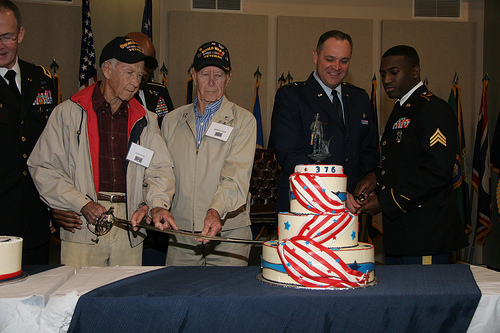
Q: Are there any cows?
A: No, there are no cows.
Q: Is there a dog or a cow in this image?
A: No, there are no cows or dogs.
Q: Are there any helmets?
A: No, there are no helmets.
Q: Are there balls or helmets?
A: No, there are no helmets or balls.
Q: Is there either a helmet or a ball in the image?
A: No, there are no helmets or balls.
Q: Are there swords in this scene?
A: Yes, there is a sword.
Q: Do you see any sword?
A: Yes, there is a sword.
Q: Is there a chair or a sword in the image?
A: Yes, there is a sword.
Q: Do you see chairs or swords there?
A: Yes, there is a sword.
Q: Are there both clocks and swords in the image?
A: No, there is a sword but no clocks.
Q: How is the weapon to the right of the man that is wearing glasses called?
A: The weapon is a sword.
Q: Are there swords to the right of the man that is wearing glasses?
A: Yes, there is a sword to the right of the man.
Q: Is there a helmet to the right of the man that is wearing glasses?
A: No, there is a sword to the right of the man.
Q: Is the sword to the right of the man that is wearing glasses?
A: Yes, the sword is to the right of the man.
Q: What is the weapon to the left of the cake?
A: The weapon is a sword.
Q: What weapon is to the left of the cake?
A: The weapon is a sword.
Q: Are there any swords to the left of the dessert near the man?
A: Yes, there is a sword to the left of the cake.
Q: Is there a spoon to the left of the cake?
A: No, there is a sword to the left of the cake.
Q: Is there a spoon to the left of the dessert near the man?
A: No, there is a sword to the left of the cake.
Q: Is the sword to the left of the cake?
A: Yes, the sword is to the left of the cake.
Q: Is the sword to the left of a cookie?
A: No, the sword is to the left of the cake.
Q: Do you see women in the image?
A: No, there are no women.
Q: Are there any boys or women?
A: No, there are no women or boys.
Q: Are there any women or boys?
A: No, there are no women or boys.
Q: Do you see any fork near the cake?
A: No, there is a man near the cake.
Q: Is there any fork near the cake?
A: No, there is a man near the cake.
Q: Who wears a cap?
A: The man wears a cap.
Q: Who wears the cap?
A: The man wears a cap.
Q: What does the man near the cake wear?
A: The man wears a cap.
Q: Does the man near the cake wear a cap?
A: Yes, the man wears a cap.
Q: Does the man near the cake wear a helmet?
A: No, the man wears a cap.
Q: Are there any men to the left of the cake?
A: Yes, there is a man to the left of the cake.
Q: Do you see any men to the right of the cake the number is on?
A: No, the man is to the left of the cake.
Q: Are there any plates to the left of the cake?
A: No, there is a man to the left of the cake.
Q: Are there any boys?
A: No, there are no boys.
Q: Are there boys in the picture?
A: No, there are no boys.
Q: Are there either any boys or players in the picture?
A: No, there are no boys or players.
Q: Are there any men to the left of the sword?
A: Yes, there is a man to the left of the sword.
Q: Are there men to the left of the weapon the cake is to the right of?
A: Yes, there is a man to the left of the sword.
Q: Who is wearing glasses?
A: The man is wearing glasses.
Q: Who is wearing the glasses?
A: The man is wearing glasses.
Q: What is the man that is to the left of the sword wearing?
A: The man is wearing glasses.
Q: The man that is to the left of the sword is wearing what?
A: The man is wearing glasses.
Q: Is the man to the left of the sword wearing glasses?
A: Yes, the man is wearing glasses.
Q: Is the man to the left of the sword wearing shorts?
A: No, the man is wearing glasses.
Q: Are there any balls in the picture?
A: No, there are no balls.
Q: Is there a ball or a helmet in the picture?
A: No, there are no balls or helmets.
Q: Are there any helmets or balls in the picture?
A: No, there are no balls or helmets.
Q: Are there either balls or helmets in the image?
A: No, there are no balls or helmets.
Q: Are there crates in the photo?
A: No, there are no crates.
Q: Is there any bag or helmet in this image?
A: No, there are no helmets or bags.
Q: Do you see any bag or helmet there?
A: No, there are no helmets or bags.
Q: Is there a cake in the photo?
A: Yes, there is a cake.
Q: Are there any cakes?
A: Yes, there is a cake.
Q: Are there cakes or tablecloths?
A: Yes, there is a cake.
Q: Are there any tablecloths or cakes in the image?
A: Yes, there is a cake.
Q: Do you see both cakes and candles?
A: No, there is a cake but no candles.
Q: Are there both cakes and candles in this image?
A: No, there is a cake but no candles.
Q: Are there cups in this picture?
A: No, there are no cups.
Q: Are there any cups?
A: No, there are no cups.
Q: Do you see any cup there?
A: No, there are no cups.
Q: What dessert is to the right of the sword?
A: The dessert is a cake.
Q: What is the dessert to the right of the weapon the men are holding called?
A: The dessert is a cake.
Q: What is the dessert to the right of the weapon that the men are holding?
A: The dessert is a cake.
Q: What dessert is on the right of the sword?
A: The dessert is a cake.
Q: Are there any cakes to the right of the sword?
A: Yes, there is a cake to the right of the sword.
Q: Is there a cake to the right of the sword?
A: Yes, there is a cake to the right of the sword.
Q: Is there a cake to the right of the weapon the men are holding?
A: Yes, there is a cake to the right of the sword.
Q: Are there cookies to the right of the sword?
A: No, there is a cake to the right of the sword.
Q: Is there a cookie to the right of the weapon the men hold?
A: No, there is a cake to the right of the sword.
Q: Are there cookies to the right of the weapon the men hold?
A: No, there is a cake to the right of the sword.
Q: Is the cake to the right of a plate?
A: No, the cake is to the right of the sword.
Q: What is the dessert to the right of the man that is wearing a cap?
A: The dessert is a cake.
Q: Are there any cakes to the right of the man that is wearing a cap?
A: Yes, there is a cake to the right of the man.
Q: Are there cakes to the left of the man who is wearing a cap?
A: No, the cake is to the right of the man.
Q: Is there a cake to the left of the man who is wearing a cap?
A: No, the cake is to the right of the man.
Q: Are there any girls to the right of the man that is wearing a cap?
A: No, there is a cake to the right of the man.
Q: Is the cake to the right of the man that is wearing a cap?
A: Yes, the cake is to the right of the man.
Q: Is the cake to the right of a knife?
A: No, the cake is to the right of the man.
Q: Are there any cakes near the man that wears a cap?
A: Yes, there is a cake near the man.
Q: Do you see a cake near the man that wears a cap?
A: Yes, there is a cake near the man.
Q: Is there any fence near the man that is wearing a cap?
A: No, there is a cake near the man.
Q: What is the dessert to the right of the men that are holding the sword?
A: The dessert is a cake.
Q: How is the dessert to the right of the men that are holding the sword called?
A: The dessert is a cake.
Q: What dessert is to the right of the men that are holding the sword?
A: The dessert is a cake.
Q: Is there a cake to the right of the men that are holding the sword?
A: Yes, there is a cake to the right of the men.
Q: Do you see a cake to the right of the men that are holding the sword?
A: Yes, there is a cake to the right of the men.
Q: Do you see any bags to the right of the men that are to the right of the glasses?
A: No, there is a cake to the right of the men.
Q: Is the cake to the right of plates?
A: No, the cake is to the right of the men.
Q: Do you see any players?
A: No, there are no players.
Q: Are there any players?
A: No, there are no players.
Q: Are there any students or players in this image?
A: No, there are no players or students.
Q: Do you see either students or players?
A: No, there are no players or students.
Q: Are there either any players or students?
A: No, there are no players or students.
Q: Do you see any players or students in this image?
A: No, there are no players or students.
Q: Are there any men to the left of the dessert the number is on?
A: Yes, there are men to the left of the cake.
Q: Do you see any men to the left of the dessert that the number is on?
A: Yes, there are men to the left of the cake.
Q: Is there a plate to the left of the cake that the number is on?
A: No, there are men to the left of the cake.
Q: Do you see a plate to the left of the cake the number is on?
A: No, there are men to the left of the cake.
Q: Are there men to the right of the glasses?
A: Yes, there are men to the right of the glasses.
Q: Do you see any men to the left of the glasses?
A: No, the men are to the right of the glasses.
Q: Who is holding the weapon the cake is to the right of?
A: The men are holding the sword.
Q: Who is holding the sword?
A: The men are holding the sword.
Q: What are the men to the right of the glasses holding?
A: The men are holding the sword.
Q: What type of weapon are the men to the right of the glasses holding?
A: The men are holding the sword.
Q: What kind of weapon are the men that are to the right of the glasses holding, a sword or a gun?
A: The men are holding a sword.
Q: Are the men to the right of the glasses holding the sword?
A: Yes, the men are holding the sword.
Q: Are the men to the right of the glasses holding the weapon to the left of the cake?
A: Yes, the men are holding the sword.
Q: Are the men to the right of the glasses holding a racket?
A: No, the men are holding the sword.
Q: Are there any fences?
A: No, there are no fences.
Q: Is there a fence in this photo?
A: No, there are no fences.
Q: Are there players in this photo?
A: No, there are no players.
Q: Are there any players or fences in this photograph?
A: No, there are no players or fences.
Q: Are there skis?
A: No, there are no skis.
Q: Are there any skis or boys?
A: No, there are no skis or boys.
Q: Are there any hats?
A: Yes, there is a hat.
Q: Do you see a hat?
A: Yes, there is a hat.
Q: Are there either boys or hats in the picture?
A: Yes, there is a hat.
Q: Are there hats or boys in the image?
A: Yes, there is a hat.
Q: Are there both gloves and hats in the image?
A: No, there is a hat but no gloves.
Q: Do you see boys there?
A: No, there are no boys.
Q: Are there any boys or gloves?
A: No, there are no boys or gloves.